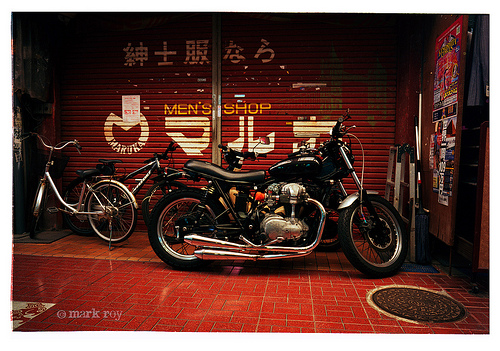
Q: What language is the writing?
A: Japanese.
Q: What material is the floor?
A: Tile.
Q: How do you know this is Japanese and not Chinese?
A: Hiragana.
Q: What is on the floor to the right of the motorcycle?
A: A manhole.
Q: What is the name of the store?
A: "Men's Shop".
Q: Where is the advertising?
A: On wall.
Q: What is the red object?
A: Door.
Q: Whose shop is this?
A: Mens.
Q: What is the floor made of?
A: Brick.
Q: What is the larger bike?
A: Motorcycle.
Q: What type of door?
A: Roll up door.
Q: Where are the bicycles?
A: Behind the motorcycle.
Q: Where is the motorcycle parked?
A: In the room.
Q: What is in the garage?
A: Bikes.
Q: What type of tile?
A: Ceramic.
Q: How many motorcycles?
A: One.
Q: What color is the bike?
A: Black.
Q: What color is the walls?
A: Red.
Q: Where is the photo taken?
A: In a bike store.